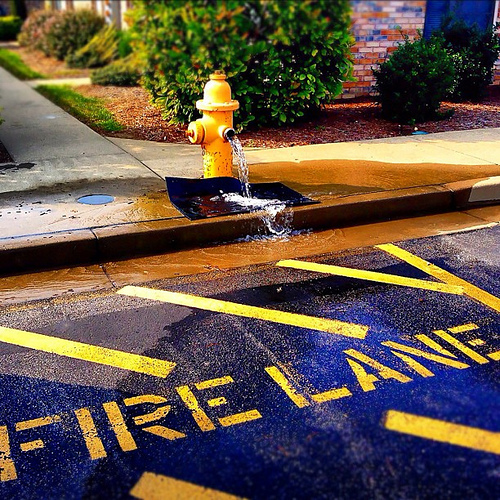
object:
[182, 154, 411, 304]
wet sidewalk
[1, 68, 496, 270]
sidewalk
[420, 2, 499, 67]
door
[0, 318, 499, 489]
words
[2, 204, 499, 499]
street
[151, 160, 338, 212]
matt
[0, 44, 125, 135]
grass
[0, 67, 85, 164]
pavement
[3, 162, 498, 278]
curb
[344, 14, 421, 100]
bricks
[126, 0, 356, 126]
leaves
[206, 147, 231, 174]
paint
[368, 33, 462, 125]
bush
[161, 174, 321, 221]
mat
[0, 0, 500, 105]
building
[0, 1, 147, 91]
plants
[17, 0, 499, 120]
building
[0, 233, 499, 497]
lines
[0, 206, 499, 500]
road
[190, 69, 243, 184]
fire hydrant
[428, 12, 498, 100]
dark-green bush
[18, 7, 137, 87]
bushes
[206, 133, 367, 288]
water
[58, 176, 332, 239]
patch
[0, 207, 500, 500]
fire lane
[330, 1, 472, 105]
wall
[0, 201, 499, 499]
ground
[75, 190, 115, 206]
hole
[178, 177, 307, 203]
floor